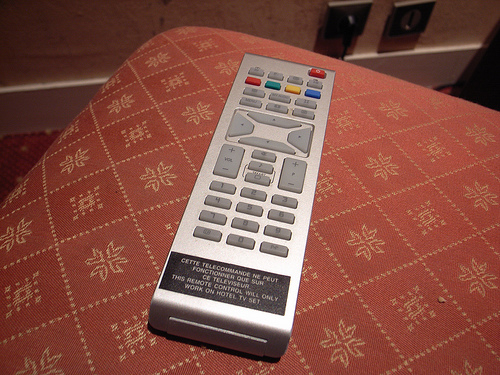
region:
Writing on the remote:
[161, 250, 291, 316]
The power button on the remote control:
[308, 66, 326, 77]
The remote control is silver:
[146, 50, 334, 359]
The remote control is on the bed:
[148, 53, 334, 358]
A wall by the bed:
[2, 2, 499, 86]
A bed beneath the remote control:
[1, 24, 499, 372]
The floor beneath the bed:
[1, 130, 58, 196]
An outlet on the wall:
[327, 4, 366, 39]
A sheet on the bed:
[0, 27, 497, 374]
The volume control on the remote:
[213, 144, 245, 176]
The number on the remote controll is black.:
[206, 176, 237, 194]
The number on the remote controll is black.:
[237, 183, 267, 202]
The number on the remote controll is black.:
[270, 190, 300, 212]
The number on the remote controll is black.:
[204, 188, 231, 210]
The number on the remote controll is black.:
[235, 198, 265, 218]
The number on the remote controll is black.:
[267, 205, 297, 227]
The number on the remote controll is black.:
[263, 219, 294, 242]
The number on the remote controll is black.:
[232, 213, 259, 232]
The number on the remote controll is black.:
[193, 204, 230, 224]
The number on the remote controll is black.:
[224, 230, 256, 251]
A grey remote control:
[194, 42, 344, 342]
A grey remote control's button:
[261, 241, 293, 261]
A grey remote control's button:
[264, 218, 294, 241]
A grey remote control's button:
[224, 231, 256, 248]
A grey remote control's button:
[185, 227, 221, 244]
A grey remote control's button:
[281, 156, 308, 195]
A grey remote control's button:
[216, 142, 241, 176]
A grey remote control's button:
[237, 200, 261, 214]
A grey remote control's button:
[200, 209, 227, 225]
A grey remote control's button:
[306, 64, 330, 78]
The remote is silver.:
[157, 33, 347, 353]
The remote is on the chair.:
[168, 40, 361, 362]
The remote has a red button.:
[300, 63, 336, 83]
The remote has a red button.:
[236, 74, 263, 86]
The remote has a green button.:
[263, 78, 283, 93]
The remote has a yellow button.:
[283, 82, 300, 94]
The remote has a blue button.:
[304, 84, 325, 100]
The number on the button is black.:
[217, 181, 232, 190]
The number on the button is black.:
[246, 188, 261, 198]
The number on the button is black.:
[278, 193, 293, 210]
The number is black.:
[208, 177, 238, 196]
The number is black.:
[239, 183, 266, 200]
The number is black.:
[272, 190, 302, 211]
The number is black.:
[266, 205, 299, 227]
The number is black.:
[236, 198, 262, 218]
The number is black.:
[202, 192, 234, 209]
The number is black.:
[197, 203, 227, 226]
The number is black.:
[232, 214, 261, 231]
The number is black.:
[261, 220, 293, 242]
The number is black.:
[226, 227, 258, 253]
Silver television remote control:
[157, 51, 322, 359]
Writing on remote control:
[157, 247, 292, 322]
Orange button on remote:
[245, 73, 258, 83]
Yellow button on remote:
[282, 77, 298, 92]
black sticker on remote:
[162, 246, 288, 322]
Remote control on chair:
[190, 53, 328, 360]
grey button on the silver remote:
[190, 225, 222, 241]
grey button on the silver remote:
[225, 231, 255, 248]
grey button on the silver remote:
[256, 240, 287, 258]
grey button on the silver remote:
[260, 223, 290, 239]